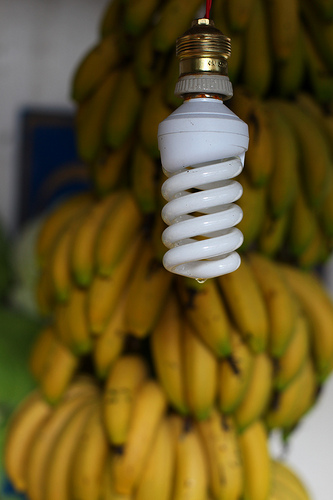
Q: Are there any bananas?
A: Yes, there are bananas.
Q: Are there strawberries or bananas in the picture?
A: Yes, there are bananas.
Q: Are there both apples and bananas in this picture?
A: No, there are bananas but no apples.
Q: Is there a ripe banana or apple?
A: Yes, there are ripe bananas.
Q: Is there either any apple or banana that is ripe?
A: Yes, the bananas are ripe.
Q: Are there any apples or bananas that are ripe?
A: Yes, the bananas are ripe.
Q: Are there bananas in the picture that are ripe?
A: Yes, there are ripe bananas.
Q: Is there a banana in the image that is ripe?
A: Yes, there are bananas that are ripe.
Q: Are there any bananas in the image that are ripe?
A: Yes, there are bananas that are ripe.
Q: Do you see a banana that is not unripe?
A: Yes, there are ripe bananas.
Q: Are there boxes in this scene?
A: No, there are no boxes.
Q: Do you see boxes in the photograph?
A: No, there are no boxes.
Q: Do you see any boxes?
A: No, there are no boxes.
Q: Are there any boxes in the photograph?
A: No, there are no boxes.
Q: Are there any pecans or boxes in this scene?
A: No, there are no boxes or pecans.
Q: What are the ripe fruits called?
A: The fruits are bananas.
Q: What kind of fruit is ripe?
A: The fruit is bananas.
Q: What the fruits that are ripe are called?
A: The fruits are bananas.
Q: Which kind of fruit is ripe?
A: The fruit is bananas.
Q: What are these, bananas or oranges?
A: These are bananas.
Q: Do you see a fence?
A: No, there are no fences.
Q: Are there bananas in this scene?
A: Yes, there is a banana.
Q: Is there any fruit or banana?
A: Yes, there is a banana.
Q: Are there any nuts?
A: No, there are no nuts.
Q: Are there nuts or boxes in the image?
A: No, there are no nuts or boxes.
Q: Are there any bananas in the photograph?
A: Yes, there is a banana.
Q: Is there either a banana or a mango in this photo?
A: Yes, there is a banana.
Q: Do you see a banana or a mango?
A: Yes, there is a banana.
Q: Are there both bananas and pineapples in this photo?
A: No, there is a banana but no pineapples.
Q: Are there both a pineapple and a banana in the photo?
A: No, there is a banana but no pineapples.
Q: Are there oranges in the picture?
A: No, there are no oranges.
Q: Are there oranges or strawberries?
A: No, there are no oranges or strawberries.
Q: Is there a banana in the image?
A: Yes, there is a banana.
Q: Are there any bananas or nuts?
A: Yes, there is a banana.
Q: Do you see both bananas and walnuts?
A: No, there is a banana but no walnuts.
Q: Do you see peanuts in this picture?
A: No, there are no peanuts.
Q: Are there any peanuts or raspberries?
A: No, there are no peanuts or raspberries.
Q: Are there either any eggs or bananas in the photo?
A: Yes, there is a banana.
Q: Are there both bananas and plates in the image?
A: No, there is a banana but no plates.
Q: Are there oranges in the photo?
A: No, there are no oranges.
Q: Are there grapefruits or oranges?
A: No, there are no oranges or grapefruits.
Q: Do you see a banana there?
A: Yes, there is a banana.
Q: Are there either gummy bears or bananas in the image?
A: Yes, there is a banana.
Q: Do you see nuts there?
A: No, there are no nuts.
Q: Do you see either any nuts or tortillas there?
A: No, there are no nuts or tortillas.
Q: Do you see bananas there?
A: Yes, there is a banana.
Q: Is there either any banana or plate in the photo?
A: Yes, there is a banana.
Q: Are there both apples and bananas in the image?
A: No, there is a banana but no apples.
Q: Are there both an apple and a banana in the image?
A: No, there is a banana but no apples.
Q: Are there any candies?
A: No, there are no candies.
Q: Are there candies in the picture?
A: No, there are no candies.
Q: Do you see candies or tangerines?
A: No, there are no candies or tangerines.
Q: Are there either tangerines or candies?
A: No, there are no candies or tangerines.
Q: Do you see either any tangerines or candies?
A: No, there are no candies or tangerines.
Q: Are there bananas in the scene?
A: Yes, there is a banana.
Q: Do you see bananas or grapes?
A: Yes, there is a banana.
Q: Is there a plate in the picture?
A: No, there are no plates.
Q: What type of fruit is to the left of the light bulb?
A: The fruit is a banana.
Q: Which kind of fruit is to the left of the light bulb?
A: The fruit is a banana.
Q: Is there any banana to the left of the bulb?
A: Yes, there is a banana to the left of the bulb.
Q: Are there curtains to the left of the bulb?
A: No, there is a banana to the left of the bulb.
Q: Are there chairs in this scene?
A: No, there are no chairs.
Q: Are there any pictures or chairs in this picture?
A: No, there are no chairs or pictures.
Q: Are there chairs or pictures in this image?
A: No, there are no chairs or pictures.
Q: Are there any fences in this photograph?
A: No, there are no fences.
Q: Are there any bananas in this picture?
A: Yes, there is a banana.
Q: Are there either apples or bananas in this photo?
A: Yes, there is a banana.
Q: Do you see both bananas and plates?
A: No, there is a banana but no plates.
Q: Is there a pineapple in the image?
A: No, there are no pineapples.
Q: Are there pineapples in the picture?
A: No, there are no pineapples.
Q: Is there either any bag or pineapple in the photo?
A: No, there are no pineapples or bags.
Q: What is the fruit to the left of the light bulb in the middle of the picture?
A: The fruit is a banana.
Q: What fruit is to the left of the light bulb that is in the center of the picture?
A: The fruit is a banana.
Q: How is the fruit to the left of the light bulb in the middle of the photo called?
A: The fruit is a banana.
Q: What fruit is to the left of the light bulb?
A: The fruit is a banana.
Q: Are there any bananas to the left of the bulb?
A: Yes, there is a banana to the left of the bulb.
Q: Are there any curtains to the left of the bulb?
A: No, there is a banana to the left of the bulb.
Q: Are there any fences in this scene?
A: No, there are no fences.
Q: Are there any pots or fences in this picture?
A: No, there are no fences or pots.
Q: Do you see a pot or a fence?
A: No, there are no fences or pots.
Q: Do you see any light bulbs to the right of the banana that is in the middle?
A: Yes, there is a light bulb to the right of the banana.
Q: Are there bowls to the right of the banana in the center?
A: No, there is a light bulb to the right of the banana.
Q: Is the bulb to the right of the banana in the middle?
A: Yes, the bulb is to the right of the banana.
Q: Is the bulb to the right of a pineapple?
A: No, the bulb is to the right of the banana.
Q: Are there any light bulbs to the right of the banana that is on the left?
A: Yes, there is a light bulb to the right of the banana.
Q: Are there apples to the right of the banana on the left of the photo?
A: No, there is a light bulb to the right of the banana.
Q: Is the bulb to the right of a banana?
A: Yes, the bulb is to the right of a banana.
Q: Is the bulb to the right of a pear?
A: No, the bulb is to the right of a banana.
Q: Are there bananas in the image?
A: Yes, there is a banana.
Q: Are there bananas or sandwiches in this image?
A: Yes, there is a banana.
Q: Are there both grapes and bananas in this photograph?
A: No, there is a banana but no grapes.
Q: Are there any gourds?
A: No, there are no gourds.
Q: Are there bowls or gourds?
A: No, there are no gourds or bowls.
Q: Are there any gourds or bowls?
A: No, there are no gourds or bowls.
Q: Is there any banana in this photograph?
A: Yes, there is a banana.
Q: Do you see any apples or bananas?
A: Yes, there is a banana.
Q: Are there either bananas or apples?
A: Yes, there is a banana.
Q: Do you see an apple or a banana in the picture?
A: Yes, there is a banana.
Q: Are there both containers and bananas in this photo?
A: No, there is a banana but no containers.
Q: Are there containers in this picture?
A: No, there are no containers.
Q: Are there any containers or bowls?
A: No, there are no containers or bowls.